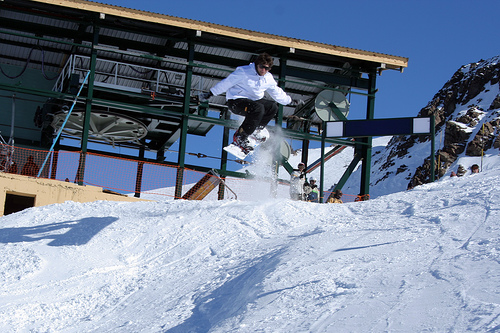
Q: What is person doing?
A: Snowboarding.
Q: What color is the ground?
A: White.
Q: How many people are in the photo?
A: One.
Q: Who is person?
A: Snowboarder.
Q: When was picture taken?
A: Daytime.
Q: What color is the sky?
A: Blue.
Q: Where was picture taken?
A: At a ski lodge.